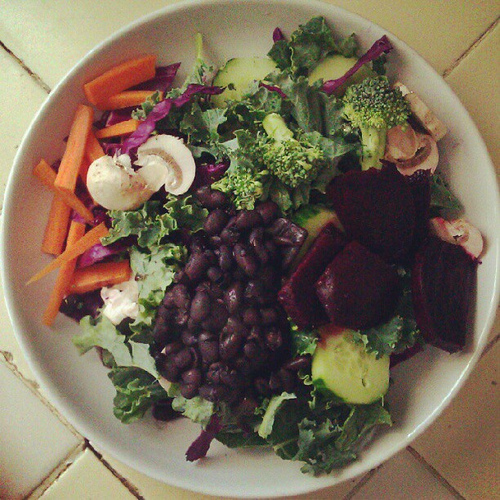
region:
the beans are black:
[155, 223, 294, 386]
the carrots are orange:
[36, 185, 131, 307]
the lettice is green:
[252, 372, 350, 462]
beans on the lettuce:
[172, 247, 284, 456]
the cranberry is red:
[301, 220, 471, 350]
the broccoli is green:
[237, 133, 374, 213]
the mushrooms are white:
[88, 135, 248, 235]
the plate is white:
[52, 351, 231, 471]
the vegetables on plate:
[60, 57, 478, 465]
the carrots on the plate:
[50, 69, 153, 341]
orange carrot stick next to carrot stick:
[82, 54, 156, 100]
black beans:
[148, 183, 315, 425]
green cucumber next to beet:
[312, 329, 391, 407]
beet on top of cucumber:
[276, 223, 352, 332]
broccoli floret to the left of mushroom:
[341, 80, 406, 172]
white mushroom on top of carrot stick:
[88, 155, 147, 212]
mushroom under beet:
[430, 217, 484, 259]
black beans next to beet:
[148, 188, 313, 410]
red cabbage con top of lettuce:
[117, 82, 234, 147]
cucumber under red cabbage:
[310, 53, 379, 83]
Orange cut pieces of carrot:
[42, 148, 90, 297]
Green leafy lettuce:
[268, 397, 365, 469]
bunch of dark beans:
[192, 256, 274, 366]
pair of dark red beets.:
[296, 244, 388, 322]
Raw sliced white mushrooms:
[87, 126, 199, 215]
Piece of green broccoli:
[244, 108, 324, 195]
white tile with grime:
[2, 361, 71, 496]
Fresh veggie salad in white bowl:
[21, 82, 499, 475]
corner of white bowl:
[28, 357, 101, 443]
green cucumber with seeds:
[307, 335, 397, 405]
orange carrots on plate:
[25, 130, 97, 267]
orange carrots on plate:
[41, 197, 101, 337]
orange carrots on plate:
[17, 235, 87, 323]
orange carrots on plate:
[10, 182, 130, 359]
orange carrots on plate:
[28, 230, 116, 377]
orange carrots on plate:
[47, 194, 74, 295]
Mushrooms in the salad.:
[86, 82, 484, 261]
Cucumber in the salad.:
[206, 30, 416, 405]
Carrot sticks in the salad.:
[25, 35, 186, 320]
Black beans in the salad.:
[146, 190, 311, 401]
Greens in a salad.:
[70, 50, 495, 475]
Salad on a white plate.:
[0, 7, 495, 493]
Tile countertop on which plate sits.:
[0, 0, 495, 497]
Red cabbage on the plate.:
[59, 62, 231, 327]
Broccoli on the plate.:
[214, 61, 410, 212]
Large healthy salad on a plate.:
[1, 3, 490, 493]